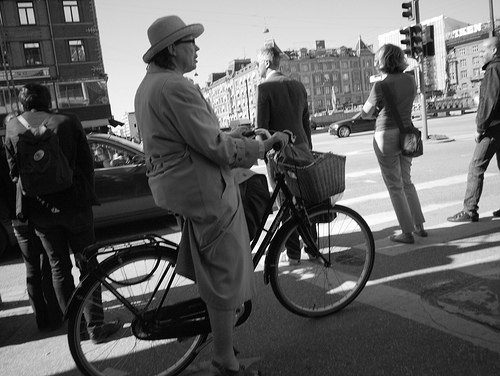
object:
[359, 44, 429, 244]
woman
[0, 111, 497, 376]
street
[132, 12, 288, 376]
woman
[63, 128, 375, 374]
bike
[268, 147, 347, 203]
basket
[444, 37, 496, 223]
man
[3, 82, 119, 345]
man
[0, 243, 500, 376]
sidewalk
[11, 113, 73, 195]
backpack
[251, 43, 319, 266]
man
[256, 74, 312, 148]
suit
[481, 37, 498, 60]
head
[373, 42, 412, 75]
head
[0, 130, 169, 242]
car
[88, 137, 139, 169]
window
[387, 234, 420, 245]
foot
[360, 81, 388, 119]
arm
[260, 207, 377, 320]
tire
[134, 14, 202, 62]
hat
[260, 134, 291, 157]
handlebars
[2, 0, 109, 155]
building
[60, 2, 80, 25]
window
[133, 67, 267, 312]
coat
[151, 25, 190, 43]
brim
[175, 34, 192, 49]
glasses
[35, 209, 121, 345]
pants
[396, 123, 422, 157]
purse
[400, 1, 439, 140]
light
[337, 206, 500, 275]
shadows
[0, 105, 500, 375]
ground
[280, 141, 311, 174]
bag